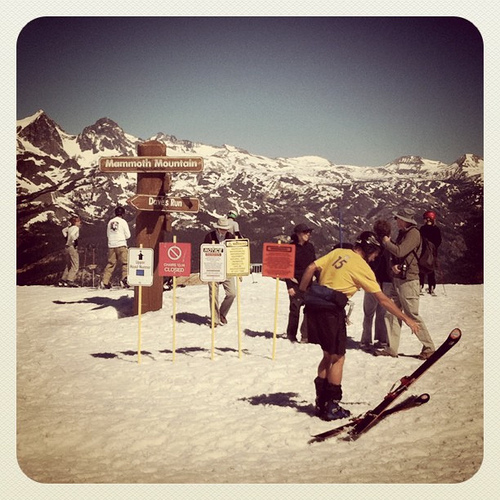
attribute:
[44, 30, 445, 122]
sky — bright blue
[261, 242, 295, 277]
banner — red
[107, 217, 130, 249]
t-shirt — white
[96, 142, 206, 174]
destination signs — brown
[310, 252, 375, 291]
shirt — yellow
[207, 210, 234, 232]
hat — gray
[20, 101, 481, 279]
mountain — rocky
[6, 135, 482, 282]
mountains — peaked, snow covered, rocky